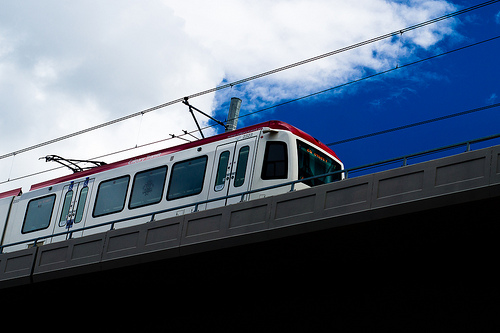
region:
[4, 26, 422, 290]
this is a train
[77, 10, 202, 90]
the sky is partly cloudy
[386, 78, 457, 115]
the sky here is a dark blue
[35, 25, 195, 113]
the clouds here are gray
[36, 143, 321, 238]
this is a commuter train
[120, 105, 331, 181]
the train runs on electricity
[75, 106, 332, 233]
the train is made of metal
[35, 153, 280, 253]
the train is white and red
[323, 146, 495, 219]
the bridge is made of stone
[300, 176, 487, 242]
the stone is gray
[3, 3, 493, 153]
dark blue sky with white clouds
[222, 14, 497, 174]
deep blue clear sky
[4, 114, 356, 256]
elevated train on platform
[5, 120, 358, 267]
red and white train on tracks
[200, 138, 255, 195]
double doors on white train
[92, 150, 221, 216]
clear window panes on train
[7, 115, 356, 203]
red roof on white train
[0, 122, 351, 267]
white train with red roof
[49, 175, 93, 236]
doors on white train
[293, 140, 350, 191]
front window on train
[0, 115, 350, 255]
Train on the bridge.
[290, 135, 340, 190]
Front window on the train.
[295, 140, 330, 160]
Sign on the window.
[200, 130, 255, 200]
doors on the train.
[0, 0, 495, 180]
Power lines in the air.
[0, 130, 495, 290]
Bridge in the forefront.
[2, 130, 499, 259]
Metal railing on the bridge.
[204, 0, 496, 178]
Blue sky in the background.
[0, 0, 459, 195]
white clouds in the background.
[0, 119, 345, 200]
Red roof on the train.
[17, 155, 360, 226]
A train running in the flyover railroad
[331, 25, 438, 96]
A blue color sky with clouds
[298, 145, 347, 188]
Front glass with wiper of the train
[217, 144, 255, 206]
Entrance of the train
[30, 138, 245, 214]
Glass windows with entrance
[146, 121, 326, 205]
Red and white color of the train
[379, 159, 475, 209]
Flyover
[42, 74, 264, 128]
Electric cable with metal pole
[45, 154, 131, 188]
Electric train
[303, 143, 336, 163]
Display board of the train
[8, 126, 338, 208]
a red and white train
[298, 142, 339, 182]
the windshield of the train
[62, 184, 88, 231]
the door of the train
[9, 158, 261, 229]
windows on the train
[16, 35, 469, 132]
wires above the train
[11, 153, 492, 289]
the cement wall next to the train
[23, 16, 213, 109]
a white cloud in the sky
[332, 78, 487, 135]
the blue part of the sky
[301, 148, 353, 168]
a sign on the bus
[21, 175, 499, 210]
a railing on the wall